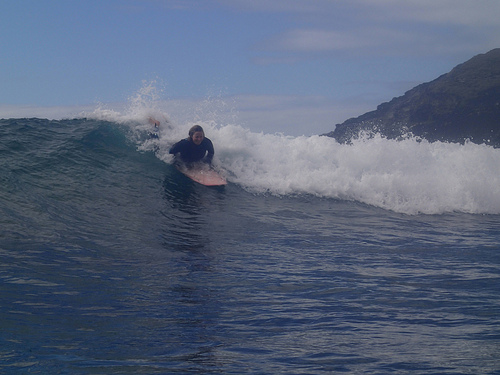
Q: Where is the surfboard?
A: On the wave.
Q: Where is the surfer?
A: On the surfboard.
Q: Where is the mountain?
A: Far behind the water.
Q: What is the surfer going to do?
A: Stand up.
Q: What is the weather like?
A: Sunny.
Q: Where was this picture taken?
A: At the beach.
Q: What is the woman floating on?
A: The ocean.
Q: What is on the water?
A: A reflection.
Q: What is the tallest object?
A: The wave.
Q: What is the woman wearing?
A: A wet suit.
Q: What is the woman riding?
A: A surfboard.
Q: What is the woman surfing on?
A: A wave.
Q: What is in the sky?
A: Clouds.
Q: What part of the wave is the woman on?
A: The top.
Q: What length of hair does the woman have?
A: Long.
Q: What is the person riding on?
A: A surf board.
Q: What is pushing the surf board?
A: An ocean wave.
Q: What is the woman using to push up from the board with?
A: Arms.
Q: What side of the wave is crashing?
A: The right side.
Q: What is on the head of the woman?
A: Hair.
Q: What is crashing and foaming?
A: A wave.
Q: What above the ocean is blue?
A: The sky.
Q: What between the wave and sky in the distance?
A: A mountian.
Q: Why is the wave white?
A: The wave is crashing.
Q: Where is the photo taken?
A: Beach.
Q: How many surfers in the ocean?
A: One.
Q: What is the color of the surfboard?
A: Orange.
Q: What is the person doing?
A: Surfing.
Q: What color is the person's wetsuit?
A: Black.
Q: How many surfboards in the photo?
A: One.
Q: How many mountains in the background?
A: One.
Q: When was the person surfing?
A: Daytime.